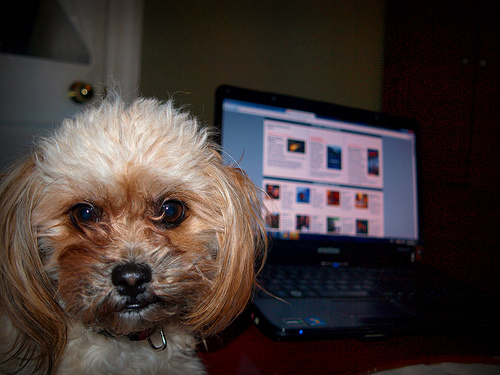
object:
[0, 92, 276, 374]
dog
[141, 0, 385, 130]
wall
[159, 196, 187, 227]
eye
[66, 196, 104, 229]
dog's eye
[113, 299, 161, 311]
dog's lips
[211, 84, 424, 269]
monitor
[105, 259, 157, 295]
dog's nose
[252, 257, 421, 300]
keyboard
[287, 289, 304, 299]
key